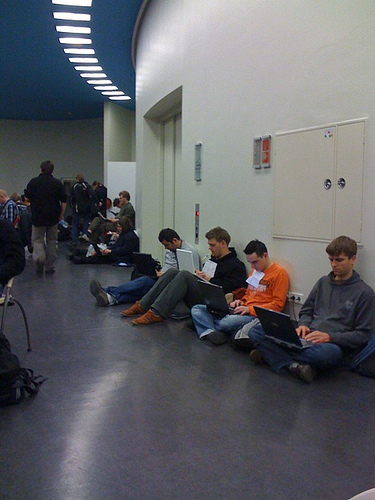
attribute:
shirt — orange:
[242, 264, 290, 314]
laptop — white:
[173, 244, 219, 287]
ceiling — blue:
[98, 9, 122, 38]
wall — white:
[140, 19, 374, 83]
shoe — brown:
[115, 291, 179, 337]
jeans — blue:
[69, 248, 163, 311]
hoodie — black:
[205, 245, 247, 292]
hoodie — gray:
[296, 270, 374, 353]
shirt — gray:
[297, 274, 374, 346]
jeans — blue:
[250, 323, 342, 368]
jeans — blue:
[193, 301, 241, 339]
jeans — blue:
[109, 268, 152, 302]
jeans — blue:
[68, 210, 89, 245]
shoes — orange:
[122, 305, 158, 325]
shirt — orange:
[229, 266, 290, 319]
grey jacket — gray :
[295, 269, 373, 358]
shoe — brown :
[132, 310, 162, 326]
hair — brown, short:
[331, 238, 357, 253]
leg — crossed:
[286, 335, 337, 362]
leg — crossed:
[251, 320, 289, 373]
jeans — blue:
[179, 297, 259, 347]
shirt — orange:
[230, 265, 296, 318]